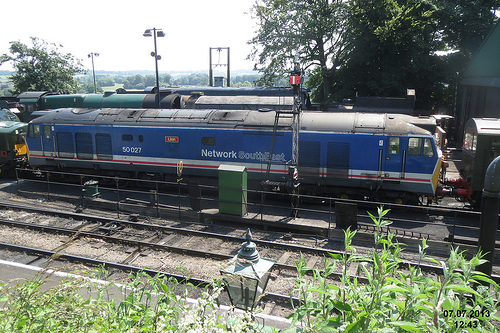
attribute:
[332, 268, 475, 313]
leaves — green 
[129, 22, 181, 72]
light — lamp 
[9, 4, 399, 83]
sky — distance, hazy 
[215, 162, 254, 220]
box — electric 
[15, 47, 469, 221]
train — blue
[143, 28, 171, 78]
post — lamp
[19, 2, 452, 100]
trees — green , Part  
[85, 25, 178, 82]
streetlight — Part  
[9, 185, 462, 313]
tracks — train   , Part 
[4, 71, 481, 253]
train — side, red stripe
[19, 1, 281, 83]
sky — Part 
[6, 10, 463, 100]
tree — distance 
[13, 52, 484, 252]
train — blue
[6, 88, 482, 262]
train — white stripe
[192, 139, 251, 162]
train — numbers 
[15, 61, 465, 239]
train — white letters 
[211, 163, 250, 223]
box — green 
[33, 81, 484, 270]
train — blue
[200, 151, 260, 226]
box — green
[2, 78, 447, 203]
train — blue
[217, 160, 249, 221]
box — green, metal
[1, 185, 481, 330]
rail — metal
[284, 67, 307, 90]
light — red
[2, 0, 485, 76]
sky — clear, white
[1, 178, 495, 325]
train tracks — empty, rusty, metal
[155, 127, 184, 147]
sign — red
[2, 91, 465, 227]
train — blue, gray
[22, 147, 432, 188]
line — red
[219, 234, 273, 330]
light post — green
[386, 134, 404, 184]
train door — blue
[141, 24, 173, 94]
lamp post — large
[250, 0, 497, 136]
tree — big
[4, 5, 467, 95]
sky — clear, white